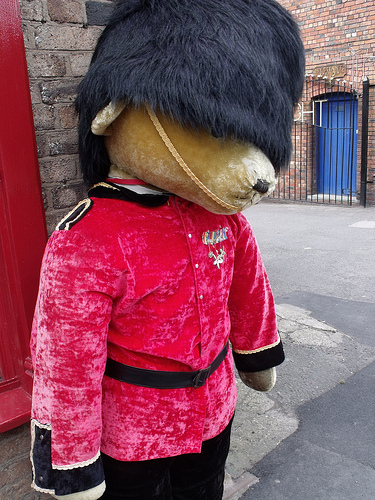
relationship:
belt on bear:
[100, 344, 233, 390] [48, 13, 373, 471]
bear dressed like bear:
[22, 0, 308, 499] [28, 0, 308, 499]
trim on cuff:
[231, 330, 281, 353] [231, 335, 285, 374]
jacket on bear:
[33, 179, 285, 499] [22, 0, 308, 499]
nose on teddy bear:
[254, 177, 269, 193] [25, 1, 312, 499]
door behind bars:
[304, 88, 367, 203] [294, 76, 365, 204]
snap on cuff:
[32, 427, 51, 443] [46, 170, 283, 499]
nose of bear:
[254, 177, 269, 193] [50, 12, 349, 272]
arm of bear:
[229, 225, 284, 391] [28, 0, 308, 499]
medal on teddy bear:
[202, 226, 232, 267] [25, 1, 312, 499]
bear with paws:
[28, 0, 308, 499] [237, 349, 283, 387]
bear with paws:
[28, 0, 308, 499] [34, 458, 114, 499]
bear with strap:
[28, 0, 308, 499] [135, 95, 255, 219]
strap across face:
[135, 95, 255, 219] [90, 21, 274, 209]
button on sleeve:
[38, 433, 44, 440] [226, 228, 285, 374]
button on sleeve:
[38, 472, 45, 482] [226, 228, 285, 374]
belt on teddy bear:
[100, 344, 233, 390] [25, 1, 312, 499]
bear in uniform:
[28, 0, 308, 499] [73, 208, 293, 417]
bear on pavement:
[28, 0, 308, 499] [0, 198, 375, 496]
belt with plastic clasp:
[100, 344, 233, 390] [192, 364, 211, 388]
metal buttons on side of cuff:
[182, 219, 220, 313] [87, 216, 286, 370]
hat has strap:
[75, 0, 306, 186] [143, 100, 243, 211]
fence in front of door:
[295, 82, 373, 193] [319, 96, 356, 194]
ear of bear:
[86, 98, 132, 137] [22, 0, 308, 499]